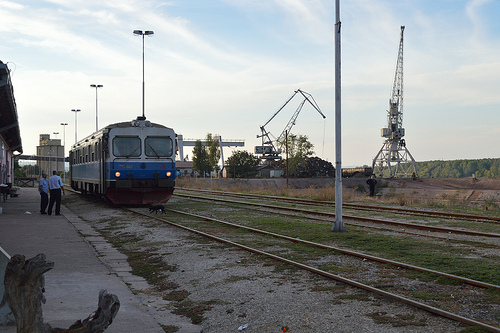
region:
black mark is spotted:
[192, 247, 207, 265]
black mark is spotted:
[199, 251, 211, 258]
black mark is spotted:
[195, 250, 215, 270]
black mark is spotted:
[198, 245, 211, 267]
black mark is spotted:
[197, 245, 205, 267]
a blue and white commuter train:
[65, 115, 175, 211]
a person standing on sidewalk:
[37, 165, 47, 212]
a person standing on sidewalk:
[47, 167, 66, 211]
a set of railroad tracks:
[130, 198, 497, 327]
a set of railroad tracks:
[182, 188, 494, 248]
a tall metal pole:
[325, 0, 348, 231]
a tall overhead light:
[130, 26, 150, 114]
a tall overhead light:
[87, 79, 104, 129]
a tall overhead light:
[66, 107, 82, 144]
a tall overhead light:
[59, 121, 68, 144]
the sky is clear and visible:
[112, 11, 352, 201]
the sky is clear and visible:
[172, 46, 282, 227]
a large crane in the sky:
[350, 15, 428, 192]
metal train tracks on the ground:
[179, 208, 444, 315]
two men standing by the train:
[32, 158, 73, 222]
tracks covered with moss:
[216, 177, 413, 292]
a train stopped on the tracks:
[44, 110, 196, 227]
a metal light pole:
[320, 0, 366, 252]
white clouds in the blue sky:
[139, 29, 256, 98]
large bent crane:
[246, 79, 331, 185]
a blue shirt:
[45, 172, 70, 193]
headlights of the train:
[103, 166, 183, 193]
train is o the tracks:
[62, 122, 190, 203]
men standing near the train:
[39, 166, 65, 216]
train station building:
[2, 47, 26, 214]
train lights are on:
[112, 159, 173, 181]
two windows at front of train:
[110, 122, 185, 164]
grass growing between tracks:
[237, 200, 365, 273]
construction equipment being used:
[252, 77, 317, 174]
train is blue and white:
[84, 122, 162, 210]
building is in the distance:
[28, 122, 53, 165]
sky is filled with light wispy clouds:
[182, 0, 457, 71]